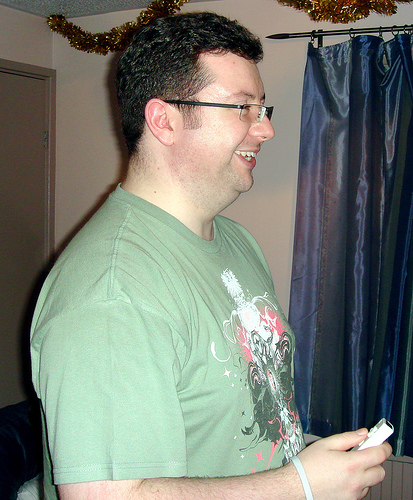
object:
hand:
[289, 419, 396, 498]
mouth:
[233, 146, 262, 170]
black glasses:
[148, 92, 275, 124]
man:
[41, 27, 360, 493]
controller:
[345, 417, 393, 450]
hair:
[113, 10, 264, 157]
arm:
[37, 312, 310, 499]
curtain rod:
[264, 22, 413, 39]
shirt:
[29, 182, 308, 498]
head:
[110, 10, 266, 219]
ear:
[143, 98, 179, 149]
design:
[209, 263, 308, 477]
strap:
[288, 452, 313, 498]